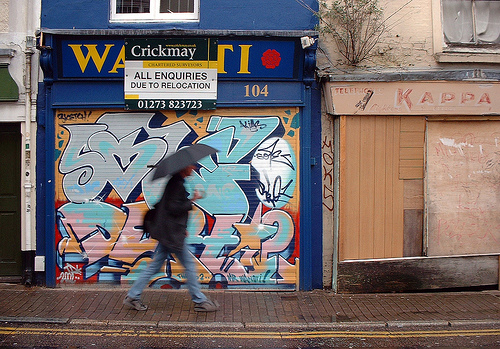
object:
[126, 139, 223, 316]
person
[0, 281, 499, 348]
sidewalk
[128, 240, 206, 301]
jeans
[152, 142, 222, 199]
umbrella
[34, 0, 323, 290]
building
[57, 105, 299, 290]
graffiti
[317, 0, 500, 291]
building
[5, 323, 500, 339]
line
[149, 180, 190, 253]
jacket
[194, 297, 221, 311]
shoe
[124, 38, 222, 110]
sign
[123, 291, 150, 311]
shoe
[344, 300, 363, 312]
brick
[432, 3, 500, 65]
panel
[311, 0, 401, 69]
tree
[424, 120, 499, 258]
door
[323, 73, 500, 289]
wall